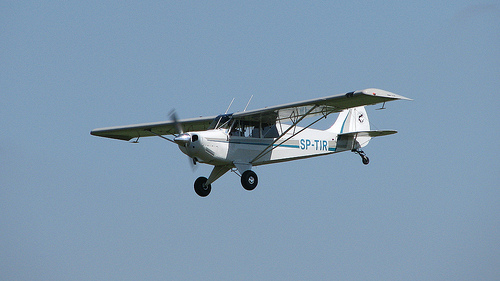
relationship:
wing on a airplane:
[197, 83, 414, 113] [74, 77, 409, 206]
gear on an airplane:
[192, 161, 258, 197] [89, 84, 416, 204]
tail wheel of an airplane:
[359, 156, 372, 165] [89, 84, 416, 204]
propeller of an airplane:
[160, 105, 210, 169] [89, 84, 416, 204]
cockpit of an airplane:
[217, 113, 282, 144] [89, 84, 416, 204]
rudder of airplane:
[332, 95, 375, 157] [71, 68, 403, 211]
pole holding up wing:
[240, 95, 324, 165] [92, 83, 418, 146]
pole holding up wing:
[245, 104, 338, 165] [92, 83, 418, 146]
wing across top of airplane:
[90, 88, 414, 142] [89, 88, 416, 197]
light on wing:
[367, 87, 384, 102] [94, 81, 382, 143]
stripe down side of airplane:
[205, 135, 337, 153] [89, 88, 416, 197]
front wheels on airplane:
[193, 176, 211, 197] [89, 88, 416, 197]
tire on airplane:
[240, 170, 259, 191] [89, 88, 416, 197]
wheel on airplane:
[355, 151, 374, 168] [89, 88, 416, 197]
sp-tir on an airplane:
[300, 139, 327, 151] [95, 75, 394, 192]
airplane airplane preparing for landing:
[89, 84, 416, 204] [111, 218, 329, 249]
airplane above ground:
[89, 84, 416, 204] [398, 137, 401, 151]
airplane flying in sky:
[89, 84, 416, 204] [6, 11, 493, 80]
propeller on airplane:
[160, 109, 218, 175] [89, 88, 416, 197]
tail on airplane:
[324, 102, 399, 167] [89, 88, 416, 197]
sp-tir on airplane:
[300, 139, 327, 151] [89, 88, 416, 197]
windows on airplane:
[232, 121, 281, 139] [89, 88, 416, 197]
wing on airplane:
[90, 88, 414, 142] [89, 88, 416, 197]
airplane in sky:
[89, 84, 416, 204] [4, 6, 491, 78]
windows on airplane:
[219, 119, 279, 140] [99, 67, 422, 239]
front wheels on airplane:
[164, 176, 293, 208] [89, 88, 416, 197]